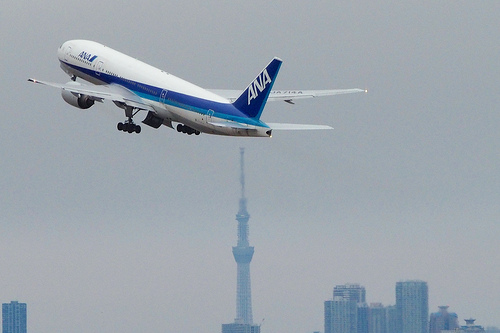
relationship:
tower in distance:
[214, 146, 267, 332] [2, 119, 498, 331]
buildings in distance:
[315, 276, 499, 333] [2, 119, 498, 331]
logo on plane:
[74, 46, 100, 64] [26, 38, 372, 142]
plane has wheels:
[26, 38, 372, 142] [118, 119, 199, 134]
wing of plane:
[26, 75, 138, 113] [26, 38, 372, 142]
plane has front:
[26, 38, 372, 142] [54, 35, 89, 74]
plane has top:
[26, 38, 372, 142] [58, 40, 232, 99]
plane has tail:
[26, 38, 372, 142] [231, 56, 297, 142]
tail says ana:
[231, 56, 297, 142] [247, 67, 273, 104]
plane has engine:
[26, 38, 372, 142] [60, 72, 96, 108]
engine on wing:
[60, 72, 96, 108] [26, 75, 138, 113]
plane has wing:
[26, 38, 372, 142] [26, 75, 138, 113]